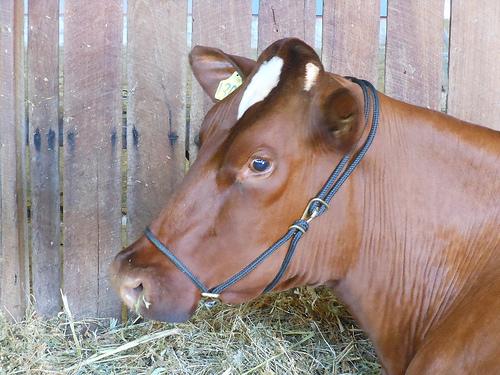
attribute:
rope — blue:
[143, 75, 380, 301]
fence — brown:
[4, 8, 173, 243]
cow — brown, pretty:
[145, 56, 497, 341]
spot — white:
[227, 56, 289, 125]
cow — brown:
[111, 35, 498, 372]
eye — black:
[243, 153, 289, 186]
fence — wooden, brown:
[3, 0, 496, 325]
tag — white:
[214, 69, 242, 99]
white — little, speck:
[305, 60, 318, 92]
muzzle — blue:
[140, 224, 218, 322]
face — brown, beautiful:
[112, 38, 362, 322]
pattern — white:
[231, 54, 286, 126]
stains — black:
[29, 122, 189, 157]